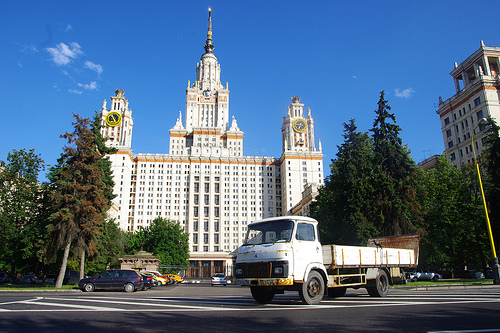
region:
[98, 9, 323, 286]
large white building with towers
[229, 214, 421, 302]
white truck in parking lot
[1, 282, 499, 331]
paved parking lot with painted white lines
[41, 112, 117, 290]
brown and green tree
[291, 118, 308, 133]
large round clock on building tower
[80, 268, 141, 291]
dark blue vehicle parked in parking lot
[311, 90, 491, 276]
group of trees growing in front of building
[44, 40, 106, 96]
lonely white clouds in the sky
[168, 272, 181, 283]
yellow car parked in parking lot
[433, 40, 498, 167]
tall white building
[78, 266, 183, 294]
long row of cars parked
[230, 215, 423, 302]
light blue truck on road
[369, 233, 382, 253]
small black bird perched on side of truck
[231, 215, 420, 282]
antique truck covered in rust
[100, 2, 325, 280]
tall white building with beautiful architecture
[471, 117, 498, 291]
tall street light beside pavement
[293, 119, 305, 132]
clock on top most story of building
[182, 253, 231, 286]
entrance to building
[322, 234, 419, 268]
flat bed of the truck enclosed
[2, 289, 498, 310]
white lines painted on road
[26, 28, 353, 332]
This is an urban setting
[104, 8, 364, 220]
this building is classical architechure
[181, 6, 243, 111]
there top of the tower has a spike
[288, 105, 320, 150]
there is a clock on the tower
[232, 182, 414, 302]
this is an old truck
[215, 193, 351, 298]
the truck cab is white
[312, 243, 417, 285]
the truck bed is made of wood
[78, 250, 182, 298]
this car is black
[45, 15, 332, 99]
the weather is partly cloudy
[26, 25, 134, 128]
these clouds are thin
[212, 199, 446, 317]
the truck is white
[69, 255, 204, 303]
the cars are parked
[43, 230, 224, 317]
the cars are parked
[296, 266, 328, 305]
tire on a truck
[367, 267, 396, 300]
tire on a truck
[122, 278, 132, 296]
tire on a car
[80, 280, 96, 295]
tire on a car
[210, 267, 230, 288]
car in a parking lot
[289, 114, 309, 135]
clock on a building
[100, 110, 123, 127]
clock on a building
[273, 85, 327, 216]
tower on a building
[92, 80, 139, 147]
tower on a building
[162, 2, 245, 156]
tower on a building